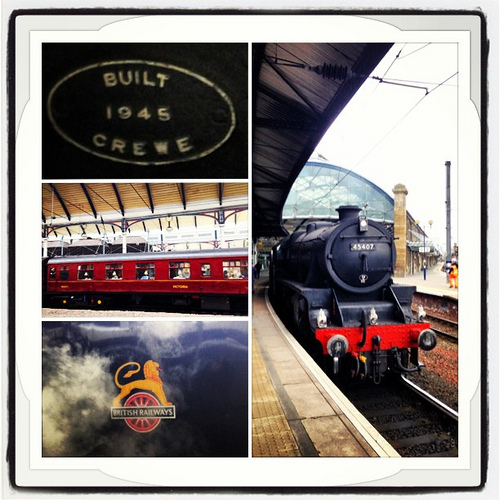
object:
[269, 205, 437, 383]
train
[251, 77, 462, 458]
station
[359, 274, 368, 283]
logo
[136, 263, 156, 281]
window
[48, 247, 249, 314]
train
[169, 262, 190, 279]
window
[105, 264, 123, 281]
window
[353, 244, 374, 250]
numbers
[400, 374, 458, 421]
tracks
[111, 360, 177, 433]
lion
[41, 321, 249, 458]
train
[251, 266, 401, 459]
platform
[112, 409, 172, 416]
name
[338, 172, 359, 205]
steam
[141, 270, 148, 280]
people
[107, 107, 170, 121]
date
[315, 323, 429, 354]
bumper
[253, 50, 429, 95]
power lines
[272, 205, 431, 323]
engine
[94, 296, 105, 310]
wheel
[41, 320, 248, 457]
clouds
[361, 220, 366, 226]
headlight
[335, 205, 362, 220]
smoke stack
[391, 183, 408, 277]
pillar